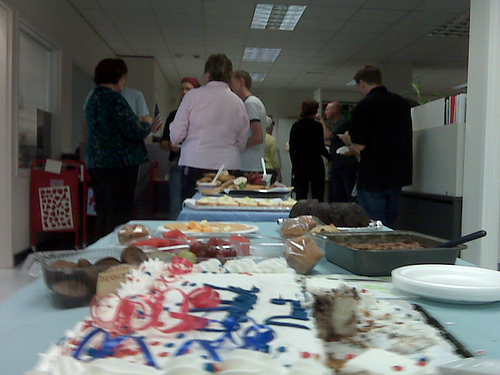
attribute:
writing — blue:
[263, 292, 311, 329]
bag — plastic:
[284, 227, 327, 277]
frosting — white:
[28, 258, 328, 373]